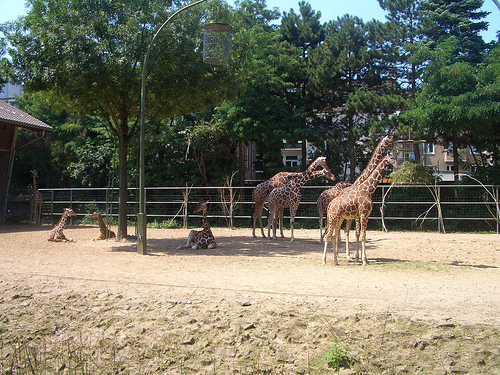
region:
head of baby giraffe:
[370, 153, 402, 185]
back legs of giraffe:
[314, 223, 356, 275]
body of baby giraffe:
[42, 212, 114, 271]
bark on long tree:
[91, 134, 158, 253]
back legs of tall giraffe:
[241, 210, 270, 234]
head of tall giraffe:
[288, 149, 336, 193]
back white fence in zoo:
[135, 165, 225, 242]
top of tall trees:
[92, 52, 220, 117]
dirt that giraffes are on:
[175, 232, 379, 313]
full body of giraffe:
[322, 157, 398, 260]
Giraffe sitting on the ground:
[171, 198, 223, 264]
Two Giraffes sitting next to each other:
[44, 187, 118, 268]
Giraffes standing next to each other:
[313, 150, 399, 274]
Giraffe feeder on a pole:
[193, 12, 252, 73]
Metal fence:
[176, 180, 270, 221]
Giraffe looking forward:
[381, 152, 406, 177]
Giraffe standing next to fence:
[21, 160, 47, 229]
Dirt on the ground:
[106, 241, 340, 331]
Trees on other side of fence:
[421, 72, 498, 211]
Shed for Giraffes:
[0, 92, 59, 170]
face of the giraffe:
[369, 132, 414, 182]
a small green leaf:
[295, 326, 355, 373]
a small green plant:
[297, 330, 382, 372]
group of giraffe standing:
[6, 137, 408, 284]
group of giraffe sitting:
[46, 134, 466, 302]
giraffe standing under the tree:
[54, 138, 486, 282]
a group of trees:
[51, 17, 491, 144]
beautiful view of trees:
[49, 7, 499, 197]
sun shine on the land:
[18, 244, 470, 373]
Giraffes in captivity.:
[236, 83, 492, 303]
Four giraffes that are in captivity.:
[184, 86, 459, 312]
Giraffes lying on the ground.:
[35, 176, 221, 291]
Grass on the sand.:
[292, 350, 354, 373]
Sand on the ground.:
[4, 226, 315, 346]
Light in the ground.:
[109, 23, 238, 303]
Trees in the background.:
[185, 4, 435, 81]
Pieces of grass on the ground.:
[37, 297, 135, 371]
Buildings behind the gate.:
[249, 130, 470, 195]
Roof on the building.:
[5, 87, 60, 143]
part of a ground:
[291, 259, 314, 266]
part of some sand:
[241, 271, 281, 338]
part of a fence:
[401, 180, 453, 227]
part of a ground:
[268, 292, 331, 344]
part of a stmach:
[331, 180, 362, 233]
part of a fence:
[437, 174, 477, 209]